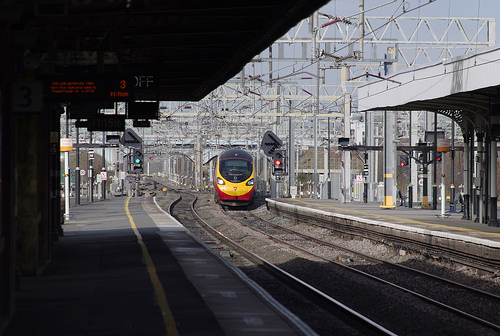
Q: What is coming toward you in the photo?
A: A train.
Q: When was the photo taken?
A: During the day.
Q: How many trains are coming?
A: One.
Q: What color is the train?
A: Yellow.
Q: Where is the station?
A: Off to the left.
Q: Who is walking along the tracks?
A: No one.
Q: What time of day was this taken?
A: Afternoon.